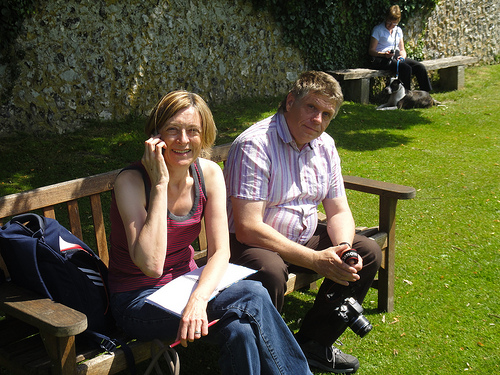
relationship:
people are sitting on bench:
[106, 73, 381, 373] [0, 136, 392, 357]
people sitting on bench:
[106, 73, 381, 373] [1, 147, 411, 372]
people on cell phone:
[106, 90, 314, 373] [146, 133, 164, 157]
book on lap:
[147, 257, 255, 320] [106, 279, 259, 339]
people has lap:
[106, 90, 314, 373] [106, 279, 259, 339]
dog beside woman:
[378, 77, 442, 110] [368, 1, 436, 102]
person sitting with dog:
[368, 4, 433, 93] [374, 79, 441, 117]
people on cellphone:
[106, 90, 314, 373] [163, 148, 164, 155]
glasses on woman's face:
[386, 20, 397, 27] [383, 10, 397, 29]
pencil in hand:
[169, 319, 218, 348] [181, 308, 209, 347]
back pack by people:
[4, 210, 124, 350] [106, 90, 314, 373]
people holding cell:
[106, 90, 314, 373] [149, 132, 167, 151]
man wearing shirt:
[223, 64, 382, 373] [221, 109, 346, 250]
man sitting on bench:
[223, 70, 382, 373] [1, 166, 418, 370]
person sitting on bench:
[368, 4, 433, 93] [336, 51, 476, 103]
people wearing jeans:
[106, 90, 314, 373] [116, 279, 314, 373]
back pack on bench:
[0, 210, 117, 350] [1, 166, 418, 370]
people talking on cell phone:
[106, 90, 314, 373] [146, 133, 164, 157]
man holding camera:
[223, 64, 382, 373] [323, 284, 373, 340]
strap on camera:
[333, 237, 360, 297] [327, 281, 376, 340]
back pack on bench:
[0, 210, 117, 350] [1, 147, 411, 372]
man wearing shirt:
[223, 70, 382, 373] [221, 109, 346, 250]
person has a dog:
[371, 3, 436, 97] [371, 74, 441, 112]